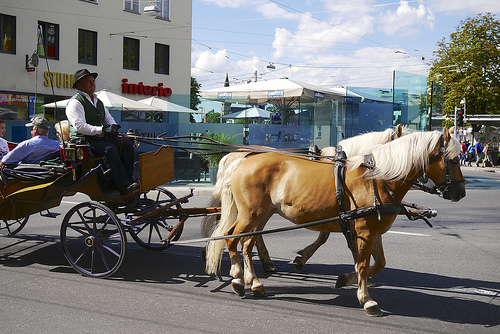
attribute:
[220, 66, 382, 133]
umrellas — numerous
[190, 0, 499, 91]
sky — blue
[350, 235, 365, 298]
leg — in the picture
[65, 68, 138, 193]
driver — in the picture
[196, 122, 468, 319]
tennis racket — in the picture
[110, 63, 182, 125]
sign — in the picture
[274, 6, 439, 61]
cloudy — in the picture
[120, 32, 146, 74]
baby — in the picture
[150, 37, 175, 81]
lettuce — in the picture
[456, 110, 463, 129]
traffic signal — in the picture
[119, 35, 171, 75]
windows — in the picture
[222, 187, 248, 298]
leg — in the picture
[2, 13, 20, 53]
window — in the picture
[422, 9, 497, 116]
green tree — in the picture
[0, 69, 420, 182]
walls — translucent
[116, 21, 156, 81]
window — in the picture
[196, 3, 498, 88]
clouds — white, puffy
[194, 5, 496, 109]
sky — blue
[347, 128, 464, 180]
mane — long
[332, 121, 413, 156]
mane — long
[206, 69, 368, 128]
tent — in the picture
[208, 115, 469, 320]
horse — in the picture, brown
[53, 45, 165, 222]
person — in the picture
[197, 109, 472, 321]
horses — in the picture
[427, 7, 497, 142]
tree — in the picture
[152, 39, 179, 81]
window — in the picture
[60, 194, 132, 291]
wheel — round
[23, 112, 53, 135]
hat — in the picture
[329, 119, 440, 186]
mane — blonde